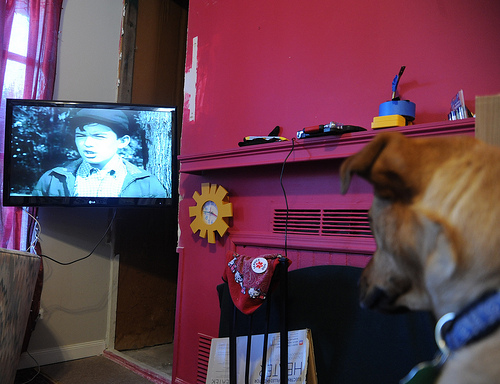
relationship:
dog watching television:
[332, 129, 499, 384] [2, 96, 181, 208]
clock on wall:
[186, 181, 239, 247] [173, 1, 498, 384]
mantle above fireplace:
[177, 113, 500, 177] [211, 236, 453, 384]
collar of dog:
[431, 290, 499, 348] [332, 129, 499, 384]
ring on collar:
[400, 310, 461, 384] [431, 290, 499, 348]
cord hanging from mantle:
[274, 137, 295, 367] [177, 113, 500, 177]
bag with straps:
[199, 261, 321, 384] [230, 259, 297, 383]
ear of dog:
[336, 131, 415, 207] [332, 129, 499, 384]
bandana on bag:
[221, 252, 292, 315] [199, 261, 321, 384]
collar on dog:
[431, 290, 499, 348] [332, 129, 499, 384]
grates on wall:
[266, 204, 397, 246] [173, 1, 498, 384]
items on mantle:
[444, 91, 468, 122] [177, 113, 500, 177]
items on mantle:
[231, 125, 290, 145] [177, 113, 500, 177]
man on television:
[33, 108, 172, 201] [2, 96, 181, 208]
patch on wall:
[181, 36, 205, 121] [173, 1, 498, 384]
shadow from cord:
[38, 297, 114, 322] [32, 203, 121, 266]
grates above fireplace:
[266, 204, 397, 246] [211, 236, 453, 384]